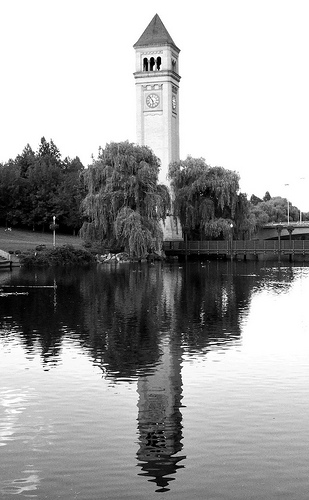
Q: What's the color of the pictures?
A: Black and white.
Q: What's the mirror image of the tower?
A: Reflection.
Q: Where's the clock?
A: Tower.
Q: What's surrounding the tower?
A: Trees.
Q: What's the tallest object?
A: Tower.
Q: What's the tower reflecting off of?
A: Water.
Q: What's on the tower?
A: Clock.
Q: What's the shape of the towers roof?
A: Triangular.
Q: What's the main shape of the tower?
A: Rectangular.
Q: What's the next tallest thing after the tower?
A: Trees.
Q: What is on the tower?
A: A clock.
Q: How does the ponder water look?
A: Serene.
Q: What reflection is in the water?
A: The clock tower's.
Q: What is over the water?
A: A bridge.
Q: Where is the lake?
A: Next to land.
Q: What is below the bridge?
A: River.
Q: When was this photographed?
A: Daytime.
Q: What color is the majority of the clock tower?
A: White.